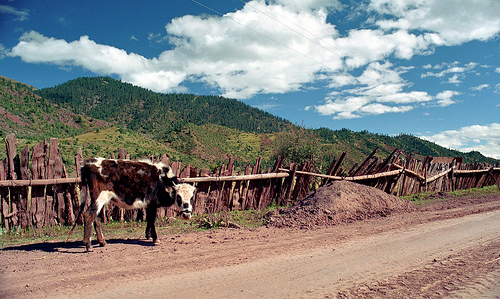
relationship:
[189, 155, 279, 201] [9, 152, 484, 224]
sticks in fence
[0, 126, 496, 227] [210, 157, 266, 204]
fence made of sticks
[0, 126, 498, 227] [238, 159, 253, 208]
fence made of sticks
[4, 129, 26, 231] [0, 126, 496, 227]
stick holding up fence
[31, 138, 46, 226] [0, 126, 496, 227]
stick holding up fence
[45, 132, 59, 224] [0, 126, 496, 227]
stick holding up fence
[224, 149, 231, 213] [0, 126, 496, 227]
stick holding up fence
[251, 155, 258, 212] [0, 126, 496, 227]
stick holding up fence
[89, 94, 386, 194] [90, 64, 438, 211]
grass covered mountains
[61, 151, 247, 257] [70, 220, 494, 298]
cow on road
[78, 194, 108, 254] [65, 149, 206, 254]
legs of cow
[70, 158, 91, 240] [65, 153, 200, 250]
tail of cow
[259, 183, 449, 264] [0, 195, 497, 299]
dirt piled on dirt road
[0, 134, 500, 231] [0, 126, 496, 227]
board hanging fence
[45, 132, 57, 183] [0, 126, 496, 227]
board leaning fence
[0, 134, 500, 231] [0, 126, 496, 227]
board dangling fence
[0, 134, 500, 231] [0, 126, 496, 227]
board swaying fence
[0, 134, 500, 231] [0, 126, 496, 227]
board swinging fence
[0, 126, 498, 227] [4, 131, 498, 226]
fence standing elephant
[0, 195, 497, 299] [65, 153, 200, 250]
dirt road lying cow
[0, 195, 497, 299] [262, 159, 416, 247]
dirt road lying mound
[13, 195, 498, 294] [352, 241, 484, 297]
dirt road lying tracks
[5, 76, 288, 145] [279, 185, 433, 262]
mountain standing dirt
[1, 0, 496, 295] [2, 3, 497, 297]
countryside observed scene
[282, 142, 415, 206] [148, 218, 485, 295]
leaning fence on road